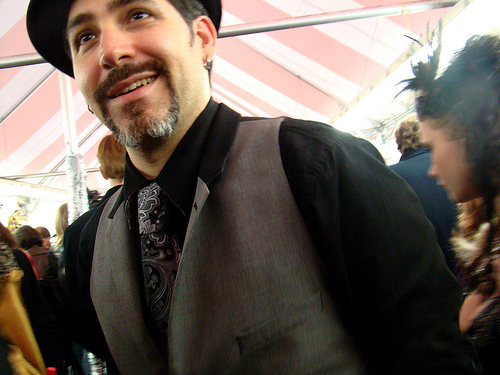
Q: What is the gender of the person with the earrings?
A: MAle.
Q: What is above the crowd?
A: Tent.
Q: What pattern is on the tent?
A: Stripes.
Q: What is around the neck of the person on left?
A: Tie.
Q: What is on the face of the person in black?
A: Facial hair.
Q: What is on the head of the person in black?
A: Hat.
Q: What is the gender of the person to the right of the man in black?
A: Female.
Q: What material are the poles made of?
A: Metal.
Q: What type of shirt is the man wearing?
A: Long sleeve.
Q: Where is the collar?
A: On shirt.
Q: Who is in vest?
A: A man.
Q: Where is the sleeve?
A: On shirt.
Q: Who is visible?
A: A man.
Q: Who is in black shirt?
A: A man.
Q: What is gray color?
A: Vest.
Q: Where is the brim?
A: On hat.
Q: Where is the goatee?
A: On man.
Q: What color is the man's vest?
A: Gray.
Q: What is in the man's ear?
A: Earring.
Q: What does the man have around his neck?
A: Necktie.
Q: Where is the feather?
A: In the woman's hair.